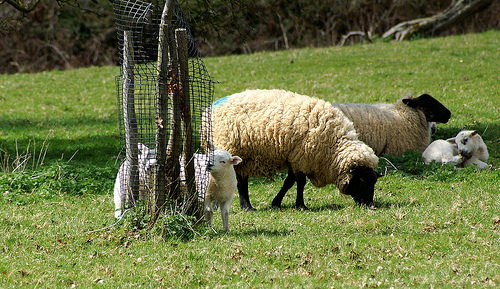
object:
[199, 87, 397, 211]
sheep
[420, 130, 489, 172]
sheep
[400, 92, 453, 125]
head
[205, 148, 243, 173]
head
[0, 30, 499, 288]
field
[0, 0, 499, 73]
bushes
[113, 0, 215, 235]
wire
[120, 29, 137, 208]
posts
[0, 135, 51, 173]
weeds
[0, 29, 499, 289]
grass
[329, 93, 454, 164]
sheep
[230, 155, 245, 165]
ear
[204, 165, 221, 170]
nose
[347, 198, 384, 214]
sheep grazing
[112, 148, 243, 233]
lamb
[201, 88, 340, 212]
body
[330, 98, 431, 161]
body